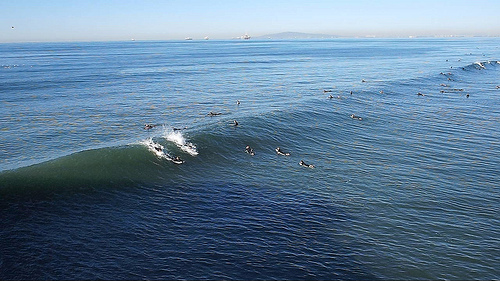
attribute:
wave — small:
[174, 99, 372, 126]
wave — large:
[4, 113, 449, 195]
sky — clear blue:
[72, 8, 341, 26]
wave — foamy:
[104, 32, 482, 254]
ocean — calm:
[2, 43, 498, 278]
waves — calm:
[119, 105, 334, 166]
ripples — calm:
[173, 220, 246, 246]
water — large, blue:
[40, 41, 477, 243]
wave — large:
[1, 53, 498, 204]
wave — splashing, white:
[95, 42, 468, 257]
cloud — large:
[195, 13, 405, 61]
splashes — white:
[142, 127, 198, 163]